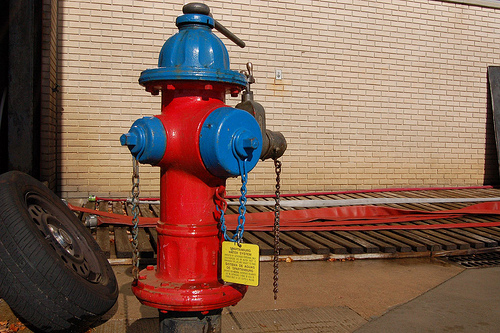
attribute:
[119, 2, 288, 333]
hydrant — red, present, blue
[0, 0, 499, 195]
building — brick, large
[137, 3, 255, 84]
top — blue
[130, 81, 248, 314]
body — red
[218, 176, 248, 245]
chain — blue, grey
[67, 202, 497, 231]
hose — red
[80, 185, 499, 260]
pallet — wooden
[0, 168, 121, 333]
tire — black, blue, slanted, spare, silver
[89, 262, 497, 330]
sidewalk — brown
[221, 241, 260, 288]
card — yellow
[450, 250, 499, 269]
grate — gray